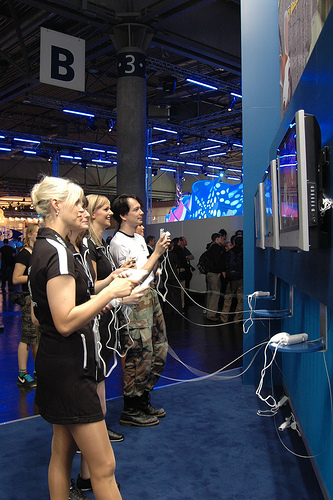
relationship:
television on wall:
[260, 159, 281, 252] [255, 10, 333, 500]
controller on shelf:
[278, 332, 310, 346] [271, 329, 324, 354]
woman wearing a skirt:
[28, 176, 131, 500] [37, 332, 106, 425]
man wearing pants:
[106, 194, 168, 429] [122, 293, 170, 396]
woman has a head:
[7, 223, 38, 389] [24, 223, 41, 248]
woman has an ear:
[28, 176, 131, 500] [50, 197, 61, 211]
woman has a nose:
[28, 176, 131, 500] [78, 207, 86, 215]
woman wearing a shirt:
[7, 223, 38, 389] [12, 248, 37, 299]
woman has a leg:
[28, 176, 131, 500] [48, 423, 79, 500]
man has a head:
[106, 194, 168, 429] [111, 192, 144, 235]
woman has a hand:
[28, 176, 131, 500] [108, 277, 134, 299]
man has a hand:
[106, 194, 168, 429] [153, 235, 171, 254]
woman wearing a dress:
[28, 176, 131, 500] [28, 227, 105, 426]